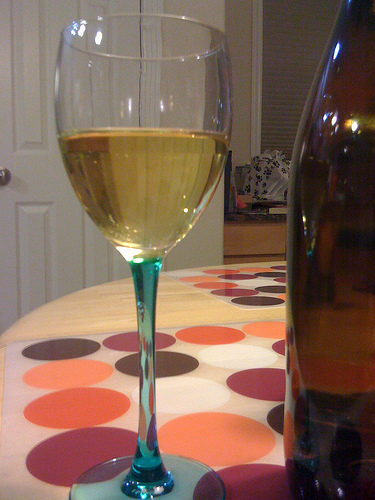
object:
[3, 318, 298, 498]
placemat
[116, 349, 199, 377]
dot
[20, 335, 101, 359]
dot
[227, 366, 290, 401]
dot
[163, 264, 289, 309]
placemat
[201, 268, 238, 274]
dot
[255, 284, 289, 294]
dot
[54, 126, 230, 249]
wine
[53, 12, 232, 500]
glass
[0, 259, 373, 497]
table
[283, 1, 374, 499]
bottle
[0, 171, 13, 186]
knob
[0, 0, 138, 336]
door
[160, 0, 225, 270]
wall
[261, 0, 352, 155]
shades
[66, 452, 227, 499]
base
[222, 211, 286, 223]
counter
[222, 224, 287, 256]
drawer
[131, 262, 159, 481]
stem